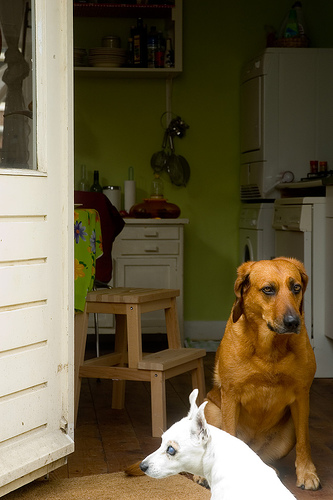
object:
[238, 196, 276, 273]
load washer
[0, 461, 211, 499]
rug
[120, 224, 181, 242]
drawer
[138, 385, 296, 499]
dog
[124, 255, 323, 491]
dog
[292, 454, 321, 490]
paw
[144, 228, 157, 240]
handle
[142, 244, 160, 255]
handle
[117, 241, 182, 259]
drawer